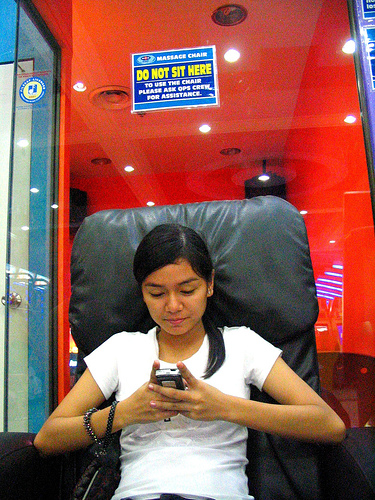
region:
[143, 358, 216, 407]
A woman has a cellphone in her hands.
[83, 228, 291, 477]
A girl sitting in a black chair.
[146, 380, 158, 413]
The girl finger nails are polished.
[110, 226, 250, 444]
The girl is looking at the phone.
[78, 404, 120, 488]
The girl has handbag around arm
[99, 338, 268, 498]
The girl is wearing a white shirt.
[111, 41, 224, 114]
A blue sign on the glass.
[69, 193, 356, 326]
The chair is black.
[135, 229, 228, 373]
The girl has long black hair.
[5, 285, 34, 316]
The doorknob is silver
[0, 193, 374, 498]
girl sitting in a black chair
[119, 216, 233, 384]
girl with long dark hair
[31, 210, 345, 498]
girl wearing a white t-shirt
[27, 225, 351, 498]
girl holding a cell phone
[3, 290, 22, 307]
silver colored door knob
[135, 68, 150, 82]
The word Do on a sign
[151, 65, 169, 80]
The word not on a sign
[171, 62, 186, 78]
The word sit on a sign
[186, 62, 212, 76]
The word here on a sign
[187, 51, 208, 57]
The word chair on a sign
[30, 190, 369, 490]
Girl with cell phone.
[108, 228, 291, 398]
Girl with long black hair.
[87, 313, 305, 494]
White short sleeve shirt.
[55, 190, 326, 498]
Girl sitting in a black chair.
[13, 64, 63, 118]
Round sticker on store window.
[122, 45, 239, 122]
Square sign on store window.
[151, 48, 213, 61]
The words MASSAGE CHAIR in white letters.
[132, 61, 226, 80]
The words DO NOT SIT HERE in yellow letters.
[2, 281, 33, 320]
Silver door knob.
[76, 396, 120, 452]
Black stretch cord around girl's arm.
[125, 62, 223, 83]
"do not sit here" written in yellow letters.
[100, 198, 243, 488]
Asian woman sitting in black chair.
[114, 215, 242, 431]
Asian woman holding cell phone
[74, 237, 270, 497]
woman wearing white short sleeved t-shirt.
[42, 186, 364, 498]
very large black chair with woman in it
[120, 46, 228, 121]
Blue massage chair sticker.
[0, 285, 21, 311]
Chrome door knob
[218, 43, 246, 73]
can light in painted red ceiling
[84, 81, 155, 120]
red painted air vent in ceiling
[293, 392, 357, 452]
elbow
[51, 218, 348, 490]
a girl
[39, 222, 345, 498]
a woman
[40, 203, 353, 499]
a girl sitting in a chair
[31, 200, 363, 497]
the girl sits in a black chair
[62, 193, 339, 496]
the chair is black leather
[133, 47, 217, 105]
a sign above the chair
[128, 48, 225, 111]
the sign states massage chair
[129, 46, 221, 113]
the yellow writing on the sign states do not sit here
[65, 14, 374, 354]
the walls behind the girl are red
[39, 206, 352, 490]
the girl looks at a cellphone